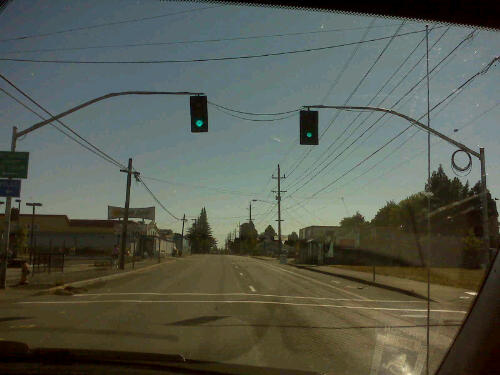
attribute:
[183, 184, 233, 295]
tree — green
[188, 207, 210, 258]
tree — tall, green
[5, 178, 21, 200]
sign — street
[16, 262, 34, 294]
fire hydrant — red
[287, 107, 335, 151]
stoplight — green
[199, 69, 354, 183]
clouds — white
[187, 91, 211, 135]
traffic light — green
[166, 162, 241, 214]
clouds — white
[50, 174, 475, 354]
road — tard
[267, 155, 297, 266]
pole — powerline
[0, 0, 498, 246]
clear sky — blue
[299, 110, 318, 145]
traffic light — green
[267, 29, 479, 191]
wires — electrical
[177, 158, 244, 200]
clouds — white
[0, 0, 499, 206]
sky — blue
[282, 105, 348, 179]
sign — green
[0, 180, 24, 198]
street sign — blue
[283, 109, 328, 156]
light — green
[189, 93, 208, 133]
stop light — green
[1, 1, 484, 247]
sky — blue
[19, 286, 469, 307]
lines — white